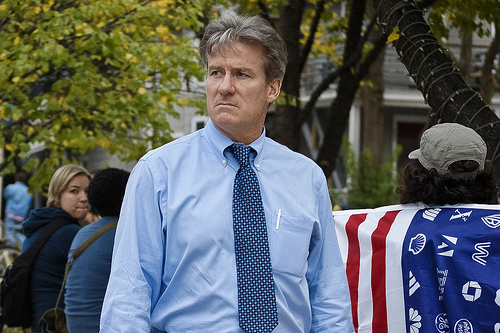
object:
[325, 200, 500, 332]
american flag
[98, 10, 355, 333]
man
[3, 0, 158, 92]
leaves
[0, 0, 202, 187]
trees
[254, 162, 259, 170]
button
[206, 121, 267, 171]
collar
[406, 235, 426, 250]
logo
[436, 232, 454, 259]
logo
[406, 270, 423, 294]
logo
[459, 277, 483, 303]
logo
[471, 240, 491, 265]
logo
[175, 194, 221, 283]
part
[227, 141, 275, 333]
brown wood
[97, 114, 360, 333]
dress shirt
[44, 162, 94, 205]
hair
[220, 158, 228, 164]
button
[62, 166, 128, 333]
person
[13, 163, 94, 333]
person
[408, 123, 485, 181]
cap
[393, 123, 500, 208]
man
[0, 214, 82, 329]
bag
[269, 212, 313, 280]
pocket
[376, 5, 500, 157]
lights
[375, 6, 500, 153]
tree branch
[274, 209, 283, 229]
pen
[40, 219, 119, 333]
bag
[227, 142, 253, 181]
knot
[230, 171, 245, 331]
edge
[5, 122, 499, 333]
background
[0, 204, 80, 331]
hoodie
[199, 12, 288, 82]
hair